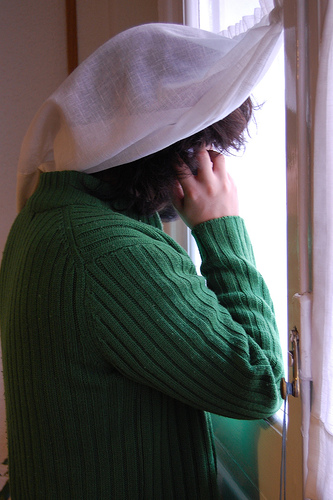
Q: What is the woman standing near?
A: Window.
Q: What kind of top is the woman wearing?
A: Green sweater.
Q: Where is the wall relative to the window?
A: Left.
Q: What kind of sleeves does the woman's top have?
A: Long.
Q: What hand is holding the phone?
A: Right.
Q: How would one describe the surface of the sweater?
A: Ribbed.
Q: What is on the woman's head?
A: Curtain.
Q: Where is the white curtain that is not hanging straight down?
A: On the woman's head.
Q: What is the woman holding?
A: A phone.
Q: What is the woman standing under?
A: The curtain.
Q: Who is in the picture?
A: A woman.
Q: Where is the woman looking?
A: Out the window.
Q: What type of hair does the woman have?
A: Dark.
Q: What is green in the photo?
A: The sweater.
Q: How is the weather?
A: Sunny.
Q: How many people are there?
A: One.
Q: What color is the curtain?
A: White.